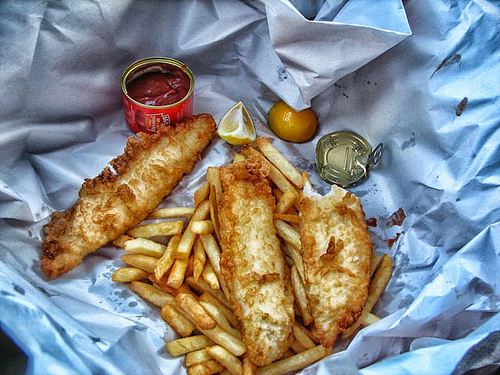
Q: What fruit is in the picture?
A: Lemon.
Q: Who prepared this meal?
A: Cook.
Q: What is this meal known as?
A: Fish and chips.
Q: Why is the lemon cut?
A: To squeeze on the fish.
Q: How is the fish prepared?
A: Fried.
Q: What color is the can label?
A: Red.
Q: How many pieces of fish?
A: Three.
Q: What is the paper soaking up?
A: Grease.